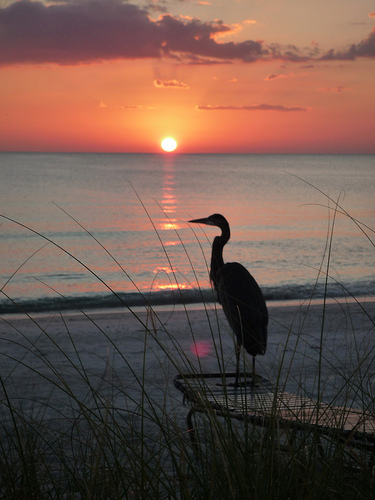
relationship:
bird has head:
[182, 212, 288, 393] [179, 210, 239, 244]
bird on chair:
[182, 212, 288, 393] [152, 365, 373, 468]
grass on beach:
[2, 357, 375, 497] [0, 302, 374, 499]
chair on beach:
[152, 365, 373, 468] [0, 302, 374, 499]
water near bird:
[0, 151, 374, 293] [182, 212, 288, 393]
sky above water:
[1, 0, 374, 154] [0, 151, 374, 293]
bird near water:
[182, 212, 288, 393] [0, 151, 374, 293]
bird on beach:
[182, 212, 288, 393] [0, 302, 374, 499]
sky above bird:
[1, 0, 374, 154] [182, 212, 288, 393]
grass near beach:
[2, 357, 375, 497] [0, 302, 374, 499]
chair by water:
[152, 365, 373, 468] [0, 151, 374, 293]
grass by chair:
[2, 357, 375, 497] [152, 365, 373, 468]